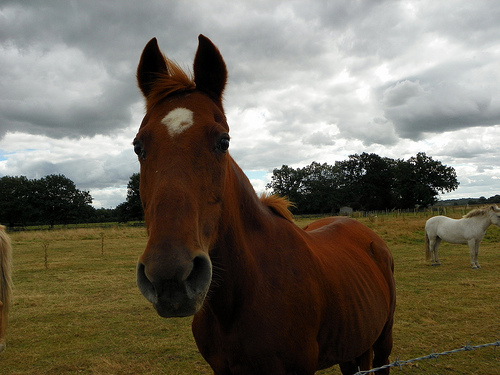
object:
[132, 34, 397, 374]
horse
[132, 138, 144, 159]
eyes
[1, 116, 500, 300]
background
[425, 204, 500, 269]
horse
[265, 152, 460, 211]
trees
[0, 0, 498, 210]
sky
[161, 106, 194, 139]
spot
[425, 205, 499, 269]
coat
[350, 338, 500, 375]
fence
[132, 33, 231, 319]
head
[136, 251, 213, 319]
nose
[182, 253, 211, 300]
nostril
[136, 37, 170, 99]
ears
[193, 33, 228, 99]
ear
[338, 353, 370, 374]
legs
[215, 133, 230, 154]
eye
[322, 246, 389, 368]
hide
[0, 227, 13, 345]
hay